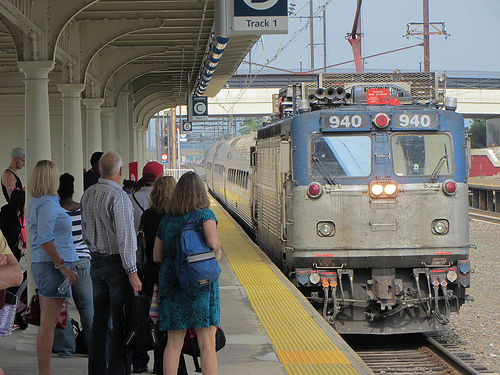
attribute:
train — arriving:
[220, 81, 482, 331]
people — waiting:
[13, 122, 226, 350]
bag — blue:
[179, 223, 222, 310]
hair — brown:
[170, 169, 211, 218]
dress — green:
[161, 206, 218, 332]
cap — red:
[142, 158, 165, 183]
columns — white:
[8, 58, 144, 198]